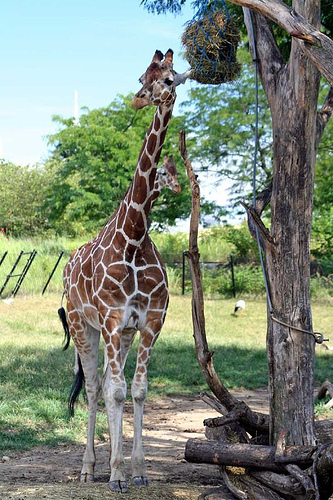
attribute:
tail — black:
[52, 304, 90, 354]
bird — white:
[231, 285, 256, 326]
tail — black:
[60, 335, 105, 425]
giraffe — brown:
[47, 43, 205, 499]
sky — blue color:
[19, 10, 102, 60]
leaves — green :
[174, 1, 330, 82]